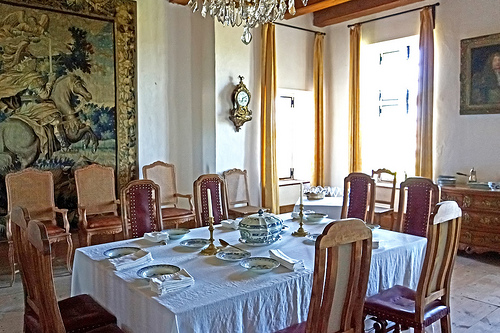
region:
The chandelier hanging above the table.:
[183, 1, 317, 40]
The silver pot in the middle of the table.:
[231, 209, 291, 244]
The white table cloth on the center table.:
[52, 213, 437, 331]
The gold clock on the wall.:
[224, 64, 257, 133]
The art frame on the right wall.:
[459, 38, 498, 111]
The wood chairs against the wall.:
[8, 148, 267, 223]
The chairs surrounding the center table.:
[3, 174, 461, 331]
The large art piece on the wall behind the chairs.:
[6, 2, 135, 205]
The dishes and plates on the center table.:
[94, 205, 358, 290]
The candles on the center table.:
[199, 182, 319, 209]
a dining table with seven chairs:
[0, 172, 471, 332]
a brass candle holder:
[190, 206, 221, 283]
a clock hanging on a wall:
[228, 64, 253, 133]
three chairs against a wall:
[19, 154, 192, 249]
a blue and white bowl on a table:
[128, 258, 189, 295]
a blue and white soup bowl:
[228, 208, 293, 266]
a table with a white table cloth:
[56, 177, 431, 329]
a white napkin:
[259, 241, 305, 284]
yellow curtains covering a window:
[261, 17, 332, 204]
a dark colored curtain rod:
[331, 4, 455, 43]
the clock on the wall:
[218, 63, 258, 162]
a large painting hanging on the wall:
[6, 4, 128, 229]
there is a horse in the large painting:
[7, 68, 102, 154]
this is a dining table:
[75, 210, 432, 316]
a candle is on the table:
[187, 185, 234, 258]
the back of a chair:
[300, 203, 382, 331]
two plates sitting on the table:
[94, 239, 193, 295]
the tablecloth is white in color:
[178, 288, 280, 322]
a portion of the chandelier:
[179, 5, 309, 46]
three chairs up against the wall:
[6, 158, 188, 237]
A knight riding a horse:
[4, 52, 104, 149]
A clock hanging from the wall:
[222, 73, 255, 134]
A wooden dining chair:
[313, 216, 369, 331]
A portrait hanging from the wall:
[461, 26, 498, 116]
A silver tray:
[235, 209, 288, 249]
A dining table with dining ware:
[69, 202, 431, 332]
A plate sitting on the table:
[236, 250, 279, 272]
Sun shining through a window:
[360, 52, 412, 169]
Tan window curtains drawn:
[255, 21, 332, 129]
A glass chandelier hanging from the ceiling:
[183, 1, 318, 47]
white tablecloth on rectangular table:
[48, 201, 445, 331]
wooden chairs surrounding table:
[23, 170, 465, 332]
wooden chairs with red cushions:
[6, 168, 462, 331]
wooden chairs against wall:
[5, 150, 265, 275]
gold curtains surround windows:
[248, 7, 442, 224]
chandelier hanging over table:
[166, 0, 331, 49]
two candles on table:
[188, 180, 318, 263]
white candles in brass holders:
[193, 183, 313, 258]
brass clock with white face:
[226, 77, 256, 133]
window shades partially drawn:
[273, 10, 423, 95]